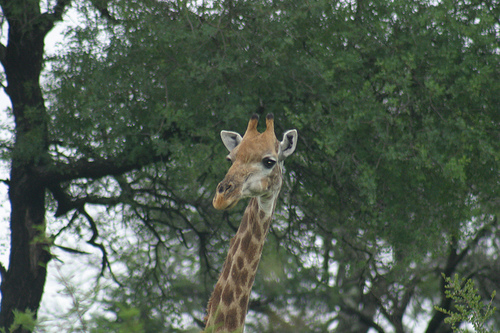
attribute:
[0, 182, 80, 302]
trunk — brown, tree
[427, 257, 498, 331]
leaves — green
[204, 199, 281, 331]
neck — long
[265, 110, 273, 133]
horn — brown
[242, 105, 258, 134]
horn — brown